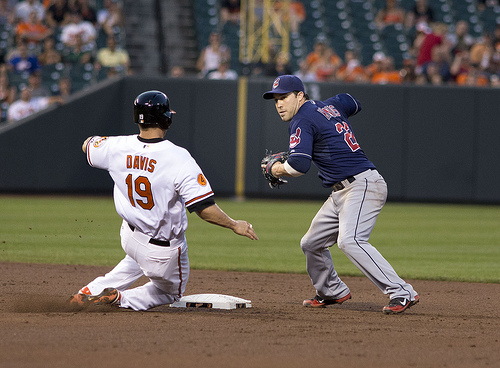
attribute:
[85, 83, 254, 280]
sliding player — in the picture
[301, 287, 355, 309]
shoe — in the picture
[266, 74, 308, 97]
cap — blue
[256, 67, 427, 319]
man — red, white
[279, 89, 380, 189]
shirt — blue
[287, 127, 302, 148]
logo — in the picture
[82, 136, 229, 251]
jersey — white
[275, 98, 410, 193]
jersey — baseball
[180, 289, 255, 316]
white — baseball base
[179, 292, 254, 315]
base — white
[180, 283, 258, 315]
base — second base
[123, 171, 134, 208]
number — red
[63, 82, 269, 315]
player — playing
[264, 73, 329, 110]
cap — blue, red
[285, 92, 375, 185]
shirt — blue, red, white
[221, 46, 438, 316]
player — baseball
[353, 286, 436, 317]
shoe — in the picture